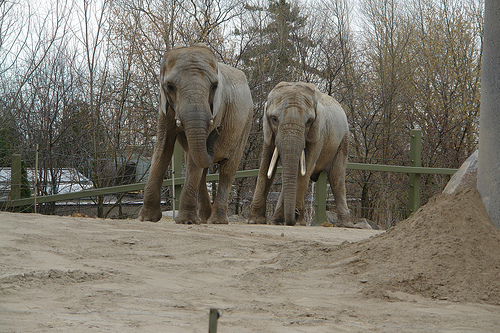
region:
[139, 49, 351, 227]
two elephants on the dirt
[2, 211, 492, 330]
a dirt pen for the elephants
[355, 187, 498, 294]
a pile of dirt on the right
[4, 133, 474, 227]
a green wood fence behind the elephants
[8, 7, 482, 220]
several trees behind the elephants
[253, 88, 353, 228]
the elephant on the right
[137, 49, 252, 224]
the elephant on the left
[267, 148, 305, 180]
the right elephant's tusks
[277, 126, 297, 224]
the right elephant's trunk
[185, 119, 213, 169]
the left elephant's trunk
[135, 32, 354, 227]
Two elphants coming up an incline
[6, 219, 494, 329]
Lots of sand on the elphant trail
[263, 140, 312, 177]
White tusks on the back elephant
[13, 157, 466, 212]
Green fencing on the enclosure.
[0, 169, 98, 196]
Roof top in the distance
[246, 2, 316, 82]
Green pine tree in the background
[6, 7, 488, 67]
Cloudy day for the elphants.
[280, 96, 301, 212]
Wrinkles on the back elphant in the trunk area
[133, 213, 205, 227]
Toe nails on the elephant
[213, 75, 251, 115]
Grey coloring on the front elephant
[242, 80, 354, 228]
A gray african elephant.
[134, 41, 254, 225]
A african elephant with short tusk.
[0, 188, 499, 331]
A brown sandy area.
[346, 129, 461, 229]
A section of green fence.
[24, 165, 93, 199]
A white building roof.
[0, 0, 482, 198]
A background of dormant trees.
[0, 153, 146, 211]
Green exhibit fencing.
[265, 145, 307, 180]
A pair of elephant tusk.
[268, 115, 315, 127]
Dark elephant eyes.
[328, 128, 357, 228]
An african elephants hind leg.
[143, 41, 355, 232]
two elephants standing outside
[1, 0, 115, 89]
tree branches with no leaves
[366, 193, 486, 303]
pile of dirt on the ground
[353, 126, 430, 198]
green fence behind the elephants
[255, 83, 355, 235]
smaller elephant with long tusks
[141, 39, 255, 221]
larger elephant with shorter tusks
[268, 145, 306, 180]
two elephant tusks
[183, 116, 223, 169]
curled elephant trunk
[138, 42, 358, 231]
two elephants looking toward the camera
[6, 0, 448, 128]
trees behind the elephants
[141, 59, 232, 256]
large elephant on dirt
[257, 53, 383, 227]
large elephant on dirt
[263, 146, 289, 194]
white ivory elephant tusk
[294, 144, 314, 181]
white ivory elephant tusk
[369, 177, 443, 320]
dirt mound on right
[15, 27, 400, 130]
tall trees in background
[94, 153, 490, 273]
green fence around pin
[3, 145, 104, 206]
building in the background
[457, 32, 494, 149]
concrete pillar on right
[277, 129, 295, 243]
long trunk of elephant